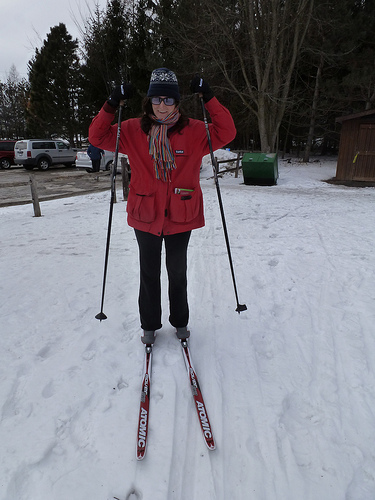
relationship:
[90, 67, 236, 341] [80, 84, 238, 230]
woman in jacket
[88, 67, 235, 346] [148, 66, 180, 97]
woman with hat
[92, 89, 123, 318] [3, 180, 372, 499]
ski on snow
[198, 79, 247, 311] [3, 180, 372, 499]
ski on snow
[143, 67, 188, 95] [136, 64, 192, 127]
hat on head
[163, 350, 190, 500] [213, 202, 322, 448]
tracks on snow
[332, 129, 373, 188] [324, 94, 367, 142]
wall on building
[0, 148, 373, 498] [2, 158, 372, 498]
snow on ground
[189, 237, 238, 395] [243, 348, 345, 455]
tracks are on snow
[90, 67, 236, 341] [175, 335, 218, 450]
woman standing on ski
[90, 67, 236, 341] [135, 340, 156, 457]
woman standing on ski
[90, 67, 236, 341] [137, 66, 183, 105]
woman wearing hat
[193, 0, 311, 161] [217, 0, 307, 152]
tree has trunk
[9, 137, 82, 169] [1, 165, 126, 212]
car parked in parking lot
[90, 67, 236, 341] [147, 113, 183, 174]
woman wearing scarf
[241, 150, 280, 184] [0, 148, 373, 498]
trash bin in snow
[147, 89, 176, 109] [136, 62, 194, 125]
sunglasses on face